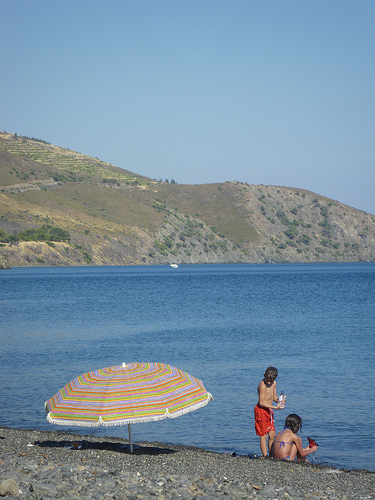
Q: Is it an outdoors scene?
A: Yes, it is outdoors.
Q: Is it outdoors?
A: Yes, it is outdoors.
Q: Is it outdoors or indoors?
A: It is outdoors.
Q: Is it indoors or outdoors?
A: It is outdoors.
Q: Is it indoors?
A: No, it is outdoors.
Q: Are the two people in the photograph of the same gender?
A: No, they are both male and female.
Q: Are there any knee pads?
A: No, there are no knee pads.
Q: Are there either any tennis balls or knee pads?
A: No, there are no knee pads or tennis balls.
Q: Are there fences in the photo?
A: No, there are no fences.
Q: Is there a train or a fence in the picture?
A: No, there are no fences or trains.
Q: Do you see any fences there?
A: No, there are no fences.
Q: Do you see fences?
A: No, there are no fences.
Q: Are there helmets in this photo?
A: No, there are no helmets.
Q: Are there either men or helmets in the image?
A: No, there are no helmets or men.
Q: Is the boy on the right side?
A: Yes, the boy is on the right of the image.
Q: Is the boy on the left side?
A: No, the boy is on the right of the image.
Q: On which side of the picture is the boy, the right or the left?
A: The boy is on the right of the image.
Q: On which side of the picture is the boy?
A: The boy is on the right of the image.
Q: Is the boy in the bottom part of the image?
A: Yes, the boy is in the bottom of the image.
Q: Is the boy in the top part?
A: No, the boy is in the bottom of the image.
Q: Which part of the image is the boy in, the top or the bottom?
A: The boy is in the bottom of the image.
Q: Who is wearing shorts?
A: The boy is wearing shorts.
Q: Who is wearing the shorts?
A: The boy is wearing shorts.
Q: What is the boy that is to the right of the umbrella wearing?
A: The boy is wearing shorts.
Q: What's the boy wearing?
A: The boy is wearing shorts.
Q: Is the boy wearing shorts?
A: Yes, the boy is wearing shorts.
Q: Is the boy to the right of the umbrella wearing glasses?
A: No, the boy is wearing shorts.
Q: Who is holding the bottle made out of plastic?
A: The boy is holding the bottle.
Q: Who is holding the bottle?
A: The boy is holding the bottle.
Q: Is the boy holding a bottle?
A: Yes, the boy is holding a bottle.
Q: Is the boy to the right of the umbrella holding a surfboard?
A: No, the boy is holding a bottle.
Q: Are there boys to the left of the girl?
A: Yes, there is a boy to the left of the girl.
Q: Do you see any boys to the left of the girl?
A: Yes, there is a boy to the left of the girl.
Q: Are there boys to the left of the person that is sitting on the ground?
A: Yes, there is a boy to the left of the girl.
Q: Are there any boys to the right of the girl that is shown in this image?
A: No, the boy is to the left of the girl.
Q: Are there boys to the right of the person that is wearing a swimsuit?
A: No, the boy is to the left of the girl.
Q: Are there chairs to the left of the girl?
A: No, there is a boy to the left of the girl.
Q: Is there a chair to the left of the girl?
A: No, there is a boy to the left of the girl.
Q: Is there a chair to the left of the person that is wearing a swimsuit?
A: No, there is a boy to the left of the girl.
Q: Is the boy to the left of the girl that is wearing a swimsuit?
A: Yes, the boy is to the left of the girl.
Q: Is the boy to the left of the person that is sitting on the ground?
A: Yes, the boy is to the left of the girl.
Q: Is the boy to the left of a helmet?
A: No, the boy is to the left of the girl.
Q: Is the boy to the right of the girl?
A: No, the boy is to the left of the girl.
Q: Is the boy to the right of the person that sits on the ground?
A: No, the boy is to the left of the girl.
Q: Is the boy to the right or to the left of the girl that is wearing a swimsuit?
A: The boy is to the left of the girl.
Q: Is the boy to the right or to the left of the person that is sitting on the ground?
A: The boy is to the left of the girl.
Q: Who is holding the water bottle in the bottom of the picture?
A: The boy is holding the water bottle.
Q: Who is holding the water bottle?
A: The boy is holding the water bottle.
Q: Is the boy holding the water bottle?
A: Yes, the boy is holding the water bottle.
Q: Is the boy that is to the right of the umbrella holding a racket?
A: No, the boy is holding the water bottle.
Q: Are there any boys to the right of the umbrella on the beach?
A: Yes, there is a boy to the right of the umbrella.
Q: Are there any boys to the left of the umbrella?
A: No, the boy is to the right of the umbrella.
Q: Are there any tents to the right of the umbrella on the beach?
A: No, there is a boy to the right of the umbrella.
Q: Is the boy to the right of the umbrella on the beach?
A: Yes, the boy is to the right of the umbrella.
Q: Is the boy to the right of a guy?
A: No, the boy is to the right of the umbrella.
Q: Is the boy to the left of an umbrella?
A: No, the boy is to the right of an umbrella.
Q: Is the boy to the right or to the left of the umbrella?
A: The boy is to the right of the umbrella.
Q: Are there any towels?
A: No, there are no towels.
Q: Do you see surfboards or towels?
A: No, there are no towels or surfboards.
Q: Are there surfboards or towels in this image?
A: No, there are no towels or surfboards.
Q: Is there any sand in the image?
A: Yes, there is sand.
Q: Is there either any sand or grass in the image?
A: Yes, there is sand.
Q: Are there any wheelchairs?
A: No, there are no wheelchairs.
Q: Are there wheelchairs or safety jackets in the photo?
A: No, there are no wheelchairs or safety jackets.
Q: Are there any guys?
A: No, there are no guys.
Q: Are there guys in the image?
A: No, there are no guys.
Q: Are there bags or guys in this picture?
A: No, there are no guys or bags.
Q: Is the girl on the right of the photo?
A: Yes, the girl is on the right of the image.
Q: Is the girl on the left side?
A: No, the girl is on the right of the image.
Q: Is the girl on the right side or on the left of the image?
A: The girl is on the right of the image.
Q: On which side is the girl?
A: The girl is on the right of the image.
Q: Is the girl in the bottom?
A: Yes, the girl is in the bottom of the image.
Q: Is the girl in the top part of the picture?
A: No, the girl is in the bottom of the image.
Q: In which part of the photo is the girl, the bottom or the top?
A: The girl is in the bottom of the image.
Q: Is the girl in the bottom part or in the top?
A: The girl is in the bottom of the image.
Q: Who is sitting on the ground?
A: The girl is sitting on the ground.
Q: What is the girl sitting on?
A: The girl is sitting on the ground.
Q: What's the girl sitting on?
A: The girl is sitting on the ground.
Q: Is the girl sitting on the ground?
A: Yes, the girl is sitting on the ground.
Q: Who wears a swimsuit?
A: The girl wears a swimsuit.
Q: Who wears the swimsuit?
A: The girl wears a swimsuit.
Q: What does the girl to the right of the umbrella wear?
A: The girl wears a swimsuit.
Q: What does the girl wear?
A: The girl wears a swimsuit.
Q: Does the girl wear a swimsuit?
A: Yes, the girl wears a swimsuit.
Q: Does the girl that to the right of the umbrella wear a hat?
A: No, the girl wears a swimsuit.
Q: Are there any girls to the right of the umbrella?
A: Yes, there is a girl to the right of the umbrella.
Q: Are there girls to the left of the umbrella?
A: No, the girl is to the right of the umbrella.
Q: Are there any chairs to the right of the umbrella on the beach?
A: No, there is a girl to the right of the umbrella.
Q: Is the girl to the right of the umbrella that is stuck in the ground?
A: Yes, the girl is to the right of the umbrella.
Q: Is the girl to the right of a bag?
A: No, the girl is to the right of the umbrella.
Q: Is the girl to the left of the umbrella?
A: No, the girl is to the right of the umbrella.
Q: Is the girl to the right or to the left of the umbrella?
A: The girl is to the right of the umbrella.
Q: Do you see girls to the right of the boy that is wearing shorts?
A: Yes, there is a girl to the right of the boy.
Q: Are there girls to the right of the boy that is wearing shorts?
A: Yes, there is a girl to the right of the boy.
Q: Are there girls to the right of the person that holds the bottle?
A: Yes, there is a girl to the right of the boy.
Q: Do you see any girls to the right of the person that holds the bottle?
A: Yes, there is a girl to the right of the boy.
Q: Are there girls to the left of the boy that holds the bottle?
A: No, the girl is to the right of the boy.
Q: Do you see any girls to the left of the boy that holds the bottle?
A: No, the girl is to the right of the boy.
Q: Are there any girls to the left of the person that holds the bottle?
A: No, the girl is to the right of the boy.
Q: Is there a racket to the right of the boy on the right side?
A: No, there is a girl to the right of the boy.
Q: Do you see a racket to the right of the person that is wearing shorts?
A: No, there is a girl to the right of the boy.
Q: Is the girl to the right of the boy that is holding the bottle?
A: Yes, the girl is to the right of the boy.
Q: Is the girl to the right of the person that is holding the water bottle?
A: Yes, the girl is to the right of the boy.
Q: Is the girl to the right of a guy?
A: No, the girl is to the right of the boy.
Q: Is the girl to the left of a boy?
A: No, the girl is to the right of a boy.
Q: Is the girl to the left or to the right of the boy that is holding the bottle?
A: The girl is to the right of the boy.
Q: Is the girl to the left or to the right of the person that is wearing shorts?
A: The girl is to the right of the boy.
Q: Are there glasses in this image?
A: No, there are no glasses.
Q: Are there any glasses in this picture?
A: No, there are no glasses.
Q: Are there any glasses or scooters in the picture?
A: No, there are no glasses or scooters.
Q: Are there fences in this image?
A: No, there are no fences.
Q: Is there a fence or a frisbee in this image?
A: No, there are no fences or frisbees.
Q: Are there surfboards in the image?
A: No, there are no surfboards.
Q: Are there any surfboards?
A: No, there are no surfboards.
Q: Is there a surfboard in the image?
A: No, there are no surfboards.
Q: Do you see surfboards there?
A: No, there are no surfboards.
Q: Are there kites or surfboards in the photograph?
A: No, there are no surfboards or kites.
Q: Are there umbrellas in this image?
A: Yes, there is an umbrella.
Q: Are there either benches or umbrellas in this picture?
A: Yes, there is an umbrella.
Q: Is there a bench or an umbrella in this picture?
A: Yes, there is an umbrella.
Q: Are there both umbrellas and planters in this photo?
A: No, there is an umbrella but no planters.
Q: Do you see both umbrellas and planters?
A: No, there is an umbrella but no planters.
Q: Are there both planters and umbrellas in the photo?
A: No, there is an umbrella but no planters.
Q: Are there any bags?
A: No, there are no bags.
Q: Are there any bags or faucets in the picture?
A: No, there are no bags or faucets.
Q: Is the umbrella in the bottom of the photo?
A: Yes, the umbrella is in the bottom of the image.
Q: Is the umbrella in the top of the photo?
A: No, the umbrella is in the bottom of the image.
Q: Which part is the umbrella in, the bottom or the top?
A: The umbrella is in the bottom of the image.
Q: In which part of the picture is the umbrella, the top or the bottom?
A: The umbrella is in the bottom of the image.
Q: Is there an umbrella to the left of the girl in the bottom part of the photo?
A: Yes, there is an umbrella to the left of the girl.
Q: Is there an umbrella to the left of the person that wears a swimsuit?
A: Yes, there is an umbrella to the left of the girl.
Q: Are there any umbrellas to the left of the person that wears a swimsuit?
A: Yes, there is an umbrella to the left of the girl.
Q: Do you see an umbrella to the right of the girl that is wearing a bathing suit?
A: No, the umbrella is to the left of the girl.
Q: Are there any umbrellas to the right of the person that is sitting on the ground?
A: No, the umbrella is to the left of the girl.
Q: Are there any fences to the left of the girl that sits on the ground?
A: No, there is an umbrella to the left of the girl.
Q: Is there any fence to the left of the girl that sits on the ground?
A: No, there is an umbrella to the left of the girl.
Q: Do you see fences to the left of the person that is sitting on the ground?
A: No, there is an umbrella to the left of the girl.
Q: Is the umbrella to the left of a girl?
A: Yes, the umbrella is to the left of a girl.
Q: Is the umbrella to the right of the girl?
A: No, the umbrella is to the left of the girl.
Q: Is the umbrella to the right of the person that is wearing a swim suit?
A: No, the umbrella is to the left of the girl.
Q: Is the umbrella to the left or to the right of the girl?
A: The umbrella is to the left of the girl.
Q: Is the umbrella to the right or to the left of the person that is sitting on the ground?
A: The umbrella is to the left of the girl.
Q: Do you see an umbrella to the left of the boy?
A: Yes, there is an umbrella to the left of the boy.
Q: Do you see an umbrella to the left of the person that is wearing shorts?
A: Yes, there is an umbrella to the left of the boy.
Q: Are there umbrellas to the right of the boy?
A: No, the umbrella is to the left of the boy.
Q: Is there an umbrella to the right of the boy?
A: No, the umbrella is to the left of the boy.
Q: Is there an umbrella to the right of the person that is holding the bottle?
A: No, the umbrella is to the left of the boy.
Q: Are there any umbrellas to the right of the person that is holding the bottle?
A: No, the umbrella is to the left of the boy.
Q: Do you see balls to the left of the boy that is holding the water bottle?
A: No, there is an umbrella to the left of the boy.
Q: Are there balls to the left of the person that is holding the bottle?
A: No, there is an umbrella to the left of the boy.